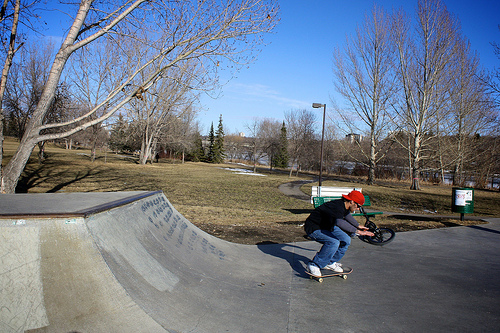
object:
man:
[294, 189, 375, 277]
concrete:
[125, 222, 268, 295]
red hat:
[341, 189, 366, 207]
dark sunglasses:
[357, 202, 362, 211]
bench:
[313, 195, 383, 216]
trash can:
[451, 187, 474, 215]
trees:
[437, 17, 484, 193]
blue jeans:
[308, 225, 352, 267]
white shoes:
[306, 262, 322, 277]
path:
[279, 179, 305, 202]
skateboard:
[304, 266, 354, 283]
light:
[311, 98, 334, 192]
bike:
[360, 207, 397, 246]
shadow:
[36, 168, 96, 193]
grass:
[162, 182, 203, 190]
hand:
[357, 230, 375, 237]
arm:
[331, 214, 360, 231]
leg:
[309, 233, 340, 264]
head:
[344, 190, 365, 213]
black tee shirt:
[302, 198, 351, 234]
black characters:
[151, 210, 158, 219]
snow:
[235, 172, 265, 177]